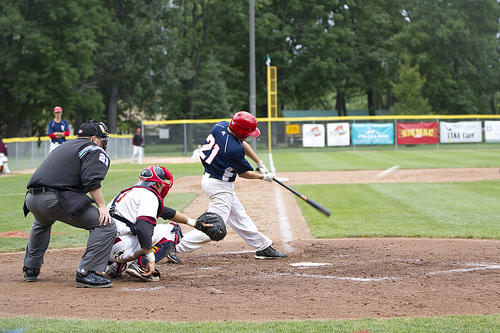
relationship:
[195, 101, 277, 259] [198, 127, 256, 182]
batter wearing blue jersey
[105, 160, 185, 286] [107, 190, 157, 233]
catcher wearing white jersey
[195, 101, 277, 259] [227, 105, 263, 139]
batter wearing a helmet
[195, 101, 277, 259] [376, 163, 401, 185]
batter has hit ball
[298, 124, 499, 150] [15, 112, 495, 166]
advertising hanging on fence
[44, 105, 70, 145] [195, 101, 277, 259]
third base coach watching batter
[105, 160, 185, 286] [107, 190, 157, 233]
catcher wearing a white jersey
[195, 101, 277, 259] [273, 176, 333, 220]
batter swinging a bat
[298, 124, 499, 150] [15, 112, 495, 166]
advertising on fence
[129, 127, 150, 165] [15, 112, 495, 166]
man standing near fence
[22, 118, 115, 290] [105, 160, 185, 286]
umpire behind catcher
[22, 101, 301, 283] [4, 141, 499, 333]
people are on a baseball field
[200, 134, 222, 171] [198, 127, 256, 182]
21 on blue jersey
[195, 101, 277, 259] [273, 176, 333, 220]
batter swung bat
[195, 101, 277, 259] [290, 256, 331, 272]
batter standing near home plate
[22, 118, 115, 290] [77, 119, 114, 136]
umpire wearing a hat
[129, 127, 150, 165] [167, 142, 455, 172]
man standing past left field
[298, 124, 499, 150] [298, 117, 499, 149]
advertising on advertising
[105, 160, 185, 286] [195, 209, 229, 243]
catcher wearing a catcher's mitt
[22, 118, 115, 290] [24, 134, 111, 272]
umpire wearing a uniform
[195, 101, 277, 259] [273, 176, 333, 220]
batter holding bat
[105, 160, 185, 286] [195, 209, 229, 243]
catcher holding catcher's mitt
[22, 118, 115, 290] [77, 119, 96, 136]
umpire wearing a hat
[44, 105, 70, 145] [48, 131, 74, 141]
third base coach crossing h arms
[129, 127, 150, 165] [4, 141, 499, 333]
man standing in a baseball field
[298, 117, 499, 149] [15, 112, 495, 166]
advertising are on fence